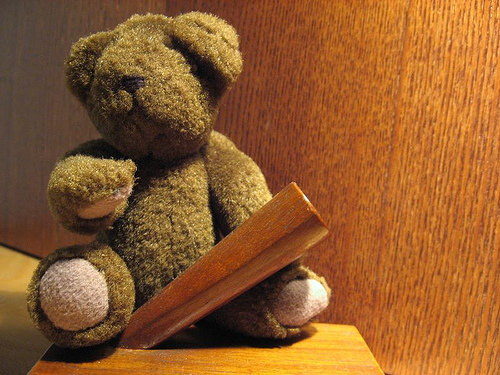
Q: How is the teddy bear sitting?
A: Upright.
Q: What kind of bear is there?
A: Teddy bear.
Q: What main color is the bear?
A: Brown.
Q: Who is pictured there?
A: No person.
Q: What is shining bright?
A: Light.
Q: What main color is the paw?
A: Beige.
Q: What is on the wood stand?
A: A teddy bear.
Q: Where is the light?
A: On the wall.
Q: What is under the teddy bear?
A: Table.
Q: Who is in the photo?
A: No people.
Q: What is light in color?
A: Feet of the bear.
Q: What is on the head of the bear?
A: Ears.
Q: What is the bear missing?
A: Eyes.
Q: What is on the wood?
A: Lines.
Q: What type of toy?
A: Stuffed toy.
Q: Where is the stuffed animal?
A: On top of wooden box.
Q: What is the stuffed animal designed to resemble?
A: Bear.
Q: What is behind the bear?
A: Wood panelled wall.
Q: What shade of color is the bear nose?
A: Black.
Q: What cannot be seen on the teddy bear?
A: Eyes.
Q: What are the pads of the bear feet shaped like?
A: Circles.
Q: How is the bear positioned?
A: Sitting.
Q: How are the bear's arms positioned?
A: With right arm outstretched before it.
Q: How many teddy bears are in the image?
A: One.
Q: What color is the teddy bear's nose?
A: Black.